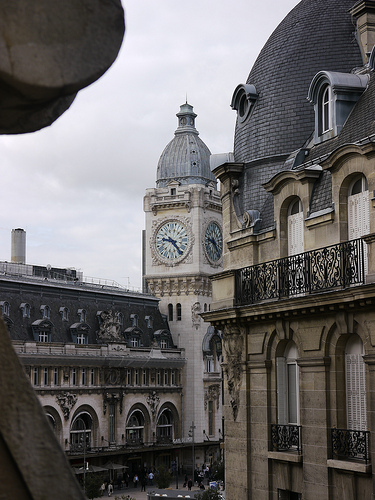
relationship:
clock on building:
[153, 217, 191, 262] [2, 103, 225, 491]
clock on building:
[153, 221, 191, 263] [2, 103, 225, 491]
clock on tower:
[153, 221, 191, 263] [145, 94, 231, 274]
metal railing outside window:
[268, 422, 302, 452] [277, 355, 301, 423]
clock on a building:
[153, 217, 191, 262] [141, 89, 221, 481]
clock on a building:
[153, 221, 191, 263] [9, 7, 371, 499]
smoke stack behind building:
[8, 217, 31, 266] [3, 257, 189, 492]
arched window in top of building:
[276, 192, 310, 295] [199, 0, 374, 498]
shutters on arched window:
[287, 212, 306, 298] [279, 192, 305, 297]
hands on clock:
[161, 229, 183, 257] [98, 204, 197, 274]